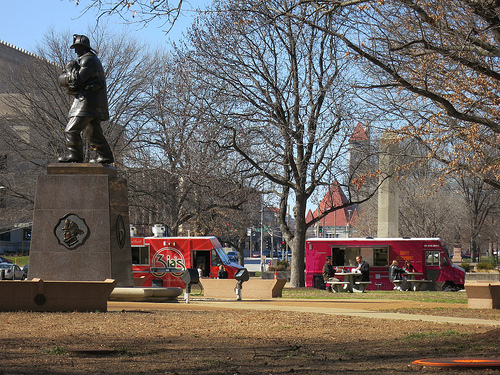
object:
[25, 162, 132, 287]
base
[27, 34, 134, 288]
statue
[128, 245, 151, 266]
window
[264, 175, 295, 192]
branch part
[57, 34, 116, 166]
fireman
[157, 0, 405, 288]
leafless tree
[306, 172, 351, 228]
roof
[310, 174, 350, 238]
building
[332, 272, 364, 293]
table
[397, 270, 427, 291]
table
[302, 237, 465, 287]
truck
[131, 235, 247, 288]
truck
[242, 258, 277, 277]
street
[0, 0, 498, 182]
sky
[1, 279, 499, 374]
ground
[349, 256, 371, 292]
people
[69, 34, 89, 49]
helmet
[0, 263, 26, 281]
car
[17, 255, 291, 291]
road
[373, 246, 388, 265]
window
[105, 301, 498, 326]
sidewalk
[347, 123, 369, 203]
building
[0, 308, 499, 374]
grass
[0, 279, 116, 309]
bench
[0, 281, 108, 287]
edge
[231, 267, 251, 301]
light